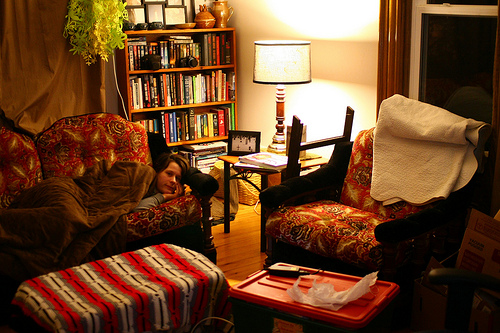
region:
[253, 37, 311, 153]
lit lamp standing on table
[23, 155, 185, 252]
woman laying on the couch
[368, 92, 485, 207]
white blanket on back of chair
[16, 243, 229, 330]
striped afghan on ottoman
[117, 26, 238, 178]
wooden bookcase in background filled with books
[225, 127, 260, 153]
black picture frame on table next to lamp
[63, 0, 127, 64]
plant hanging next to the bookcase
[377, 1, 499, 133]
window with a wooden frame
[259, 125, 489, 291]
chair with dark arms and patterned cushions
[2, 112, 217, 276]
couch with dark arms and patterned cushions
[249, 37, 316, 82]
it is a lamp on the table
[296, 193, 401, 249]
it is a red and black chair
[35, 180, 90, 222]
the woman has a brown cover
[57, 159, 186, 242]
a woman is laying down on the sofa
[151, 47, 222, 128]
books on a bookshelf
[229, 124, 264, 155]
a black picture frame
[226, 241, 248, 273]
the floor is brown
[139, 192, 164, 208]
woman is wearing grey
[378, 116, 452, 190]
a white clothe on the chair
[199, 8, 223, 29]
pots on the book shelf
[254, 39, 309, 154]
table lamp on end table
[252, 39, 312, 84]
white lampshade on table lamp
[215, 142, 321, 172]
wood top of end table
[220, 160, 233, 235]
end table has dark legs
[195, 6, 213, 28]
brown jug on top of bookcase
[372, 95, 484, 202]
folded white blanket on chair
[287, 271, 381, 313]
white crumpled paper on storage box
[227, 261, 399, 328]
lid of storage box is red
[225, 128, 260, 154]
black picture fame on end table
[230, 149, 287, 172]
stack of magazines on end table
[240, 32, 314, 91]
a beautiful bed lamp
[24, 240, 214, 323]
a beautiful cloth on table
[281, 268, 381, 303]
a small piece of paper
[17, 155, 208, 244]
a beautiful young lady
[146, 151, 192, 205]
cute face of a girl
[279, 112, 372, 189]
wooden chair in home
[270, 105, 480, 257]
a beautiful chair in home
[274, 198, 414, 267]
sponge bed in the chair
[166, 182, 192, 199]
hand of a young lady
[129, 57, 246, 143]
few books placed in the rack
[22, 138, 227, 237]
lady laying on the couch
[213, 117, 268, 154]
black picture frame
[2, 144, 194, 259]
brown blanket covering woman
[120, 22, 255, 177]
a full book shelf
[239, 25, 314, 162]
a bright lamp on table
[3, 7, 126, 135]
tan curtains covering window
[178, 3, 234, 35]
light brown pottery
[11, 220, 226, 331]
a knitted blanket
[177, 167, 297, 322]
floor made of wood